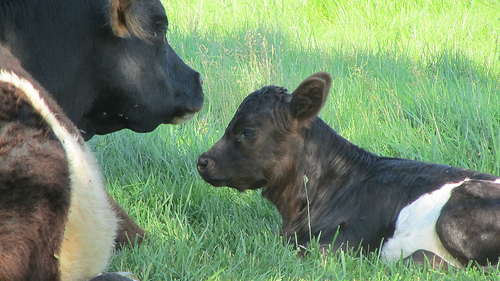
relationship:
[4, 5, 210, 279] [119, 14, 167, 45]
cow has eye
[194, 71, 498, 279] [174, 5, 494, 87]
calf lying in grass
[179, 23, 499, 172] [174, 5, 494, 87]
shadow on grass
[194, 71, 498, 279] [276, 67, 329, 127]
calf has ears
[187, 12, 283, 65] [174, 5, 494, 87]
weeds in grass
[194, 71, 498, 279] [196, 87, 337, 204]
calf has head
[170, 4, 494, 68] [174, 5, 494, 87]
sunlight on grass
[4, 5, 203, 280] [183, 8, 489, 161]
cow are in field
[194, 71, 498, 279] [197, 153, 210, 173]
calf has nostril